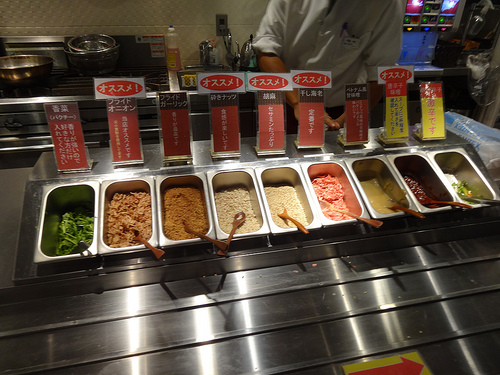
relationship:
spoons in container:
[67, 187, 499, 267] [27, 144, 499, 268]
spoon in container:
[75, 244, 98, 277] [432, 152, 494, 208]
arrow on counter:
[356, 331, 418, 372] [300, 318, 460, 368]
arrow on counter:
[342, 352, 433, 374] [317, 328, 467, 369]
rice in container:
[276, 182, 296, 223] [249, 150, 318, 250]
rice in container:
[160, 185, 209, 245] [153, 168, 215, 245]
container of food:
[37, 181, 104, 256] [52, 187, 84, 246]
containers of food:
[102, 169, 217, 254] [104, 182, 202, 238]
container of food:
[201, 141, 323, 251] [199, 154, 291, 223]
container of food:
[299, 157, 372, 232] [312, 172, 351, 219]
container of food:
[394, 150, 452, 225] [403, 145, 472, 225]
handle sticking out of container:
[131, 236, 168, 258] [299, 145, 370, 242]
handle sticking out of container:
[184, 220, 226, 248] [253, 163, 323, 235]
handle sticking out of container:
[218, 210, 243, 259] [206, 163, 270, 240]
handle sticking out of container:
[278, 207, 309, 235] [153, 168, 215, 245]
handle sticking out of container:
[335, 206, 383, 228] [98, 175, 158, 257]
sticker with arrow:
[339, 350, 433, 373] [351, 353, 420, 373]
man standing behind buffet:
[250, 0, 406, 133] [29, 148, 498, 264]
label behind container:
[87, 67, 157, 104] [88, 163, 163, 255]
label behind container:
[187, 61, 246, 94] [197, 160, 278, 249]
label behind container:
[240, 65, 297, 101] [379, 143, 464, 225]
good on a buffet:
[48, 163, 471, 258] [29, 148, 498, 264]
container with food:
[7, 130, 499, 289] [31, 148, 496, 260]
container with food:
[208, 160, 269, 253] [214, 180, 259, 224]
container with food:
[382, 150, 465, 216] [219, 186, 258, 233]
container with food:
[344, 148, 414, 223] [361, 174, 393, 205]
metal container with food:
[383, 148, 454, 220] [409, 179, 433, 207]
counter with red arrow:
[2, 228, 498, 373] [350, 347, 426, 373]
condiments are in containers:
[47, 181, 91, 255] [32, 139, 490, 268]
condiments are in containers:
[104, 174, 153, 250] [32, 139, 490, 268]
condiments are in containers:
[211, 161, 261, 239] [32, 139, 490, 268]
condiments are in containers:
[302, 161, 362, 221] [32, 139, 490, 268]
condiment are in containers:
[53, 202, 96, 257] [32, 139, 490, 268]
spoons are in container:
[422, 200, 459, 210] [212, 168, 264, 244]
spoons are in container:
[328, 203, 380, 230] [212, 168, 264, 244]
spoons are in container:
[280, 209, 310, 231] [212, 168, 264, 244]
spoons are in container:
[228, 208, 242, 245] [212, 168, 264, 244]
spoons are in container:
[136, 232, 163, 255] [212, 168, 264, 244]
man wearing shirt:
[250, 0, 406, 133] [249, 0, 407, 97]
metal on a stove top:
[61, 32, 118, 65] [0, 35, 170, 98]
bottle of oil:
[165, 23, 184, 71] [166, 53, 195, 71]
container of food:
[98, 175, 158, 257] [45, 174, 458, 240]